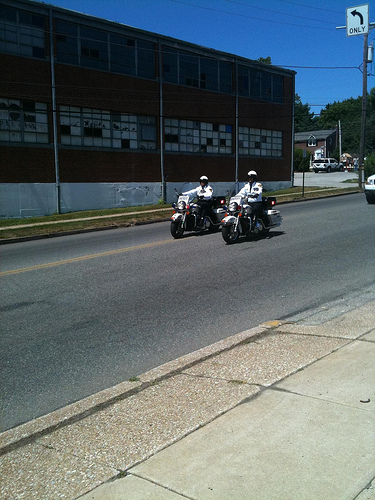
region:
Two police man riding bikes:
[165, 161, 282, 249]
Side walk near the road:
[193, 389, 328, 460]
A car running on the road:
[338, 162, 373, 209]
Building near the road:
[15, 38, 266, 154]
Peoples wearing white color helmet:
[195, 167, 261, 185]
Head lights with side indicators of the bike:
[175, 201, 242, 216]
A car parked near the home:
[314, 155, 340, 174]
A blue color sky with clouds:
[239, 7, 319, 40]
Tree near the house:
[344, 101, 363, 137]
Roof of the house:
[295, 129, 328, 138]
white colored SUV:
[308, 154, 349, 175]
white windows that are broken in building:
[185, 119, 213, 153]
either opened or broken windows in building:
[57, 13, 127, 77]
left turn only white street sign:
[340, 2, 371, 38]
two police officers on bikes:
[166, 162, 286, 246]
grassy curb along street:
[0, 182, 325, 247]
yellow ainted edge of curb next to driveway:
[252, 313, 292, 336]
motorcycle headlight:
[224, 199, 242, 213]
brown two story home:
[295, 126, 343, 177]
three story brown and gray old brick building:
[1, 0, 305, 229]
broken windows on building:
[53, 104, 162, 164]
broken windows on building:
[163, 113, 236, 159]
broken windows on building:
[239, 126, 281, 156]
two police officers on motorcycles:
[156, 165, 279, 245]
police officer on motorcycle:
[223, 167, 286, 265]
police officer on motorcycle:
[156, 156, 219, 240]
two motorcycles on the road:
[173, 158, 286, 251]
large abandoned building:
[1, 0, 297, 195]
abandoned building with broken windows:
[0, 0, 298, 211]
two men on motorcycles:
[167, 164, 284, 254]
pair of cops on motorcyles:
[153, 169, 286, 247]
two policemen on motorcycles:
[162, 156, 278, 253]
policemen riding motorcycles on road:
[154, 159, 286, 240]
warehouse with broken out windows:
[3, 93, 288, 173]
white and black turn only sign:
[341, 3, 371, 38]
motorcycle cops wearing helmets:
[154, 155, 284, 243]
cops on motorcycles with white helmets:
[167, 149, 287, 247]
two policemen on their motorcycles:
[162, 155, 280, 243]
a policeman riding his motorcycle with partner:
[161, 162, 282, 245]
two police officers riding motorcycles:
[159, 157, 287, 247]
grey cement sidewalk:
[2, 294, 373, 499]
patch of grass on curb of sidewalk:
[123, 374, 142, 386]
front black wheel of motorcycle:
[166, 210, 187, 239]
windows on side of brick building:
[1, 93, 289, 179]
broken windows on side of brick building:
[70, 114, 137, 135]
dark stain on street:
[2, 294, 58, 320]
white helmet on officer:
[190, 172, 210, 188]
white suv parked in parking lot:
[307, 149, 343, 176]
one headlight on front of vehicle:
[357, 174, 374, 188]